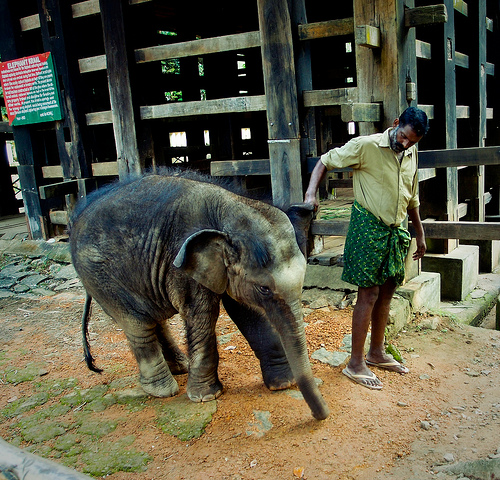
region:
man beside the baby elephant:
[192, 129, 429, 400]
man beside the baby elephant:
[211, 103, 440, 406]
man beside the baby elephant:
[188, 113, 457, 413]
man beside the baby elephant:
[185, 78, 440, 432]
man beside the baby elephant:
[185, 108, 435, 434]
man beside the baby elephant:
[214, 90, 437, 427]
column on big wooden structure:
[0, 0, 52, 240]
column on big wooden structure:
[30, 0, 97, 196]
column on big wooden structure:
[96, 0, 151, 181]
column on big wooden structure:
[254, 0, 306, 243]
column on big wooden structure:
[350, 0, 418, 138]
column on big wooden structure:
[427, 0, 458, 252]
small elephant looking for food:
[73, 173, 330, 425]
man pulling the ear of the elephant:
[305, 93, 433, 388]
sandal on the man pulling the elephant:
[339, 363, 384, 389]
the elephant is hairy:
[60, 171, 362, 471]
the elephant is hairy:
[54, 150, 346, 451]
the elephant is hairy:
[54, 169, 334, 454]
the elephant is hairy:
[57, 178, 334, 438]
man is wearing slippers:
[338, 323, 413, 400]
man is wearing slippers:
[340, 334, 406, 394]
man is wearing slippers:
[330, 340, 407, 397]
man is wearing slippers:
[326, 345, 421, 400]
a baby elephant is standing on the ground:
[67, 166, 329, 421]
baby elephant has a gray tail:
[79, 292, 104, 374]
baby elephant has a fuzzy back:
[69, 166, 242, 251]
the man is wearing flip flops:
[298, 107, 427, 389]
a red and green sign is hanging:
[0, 50, 62, 127]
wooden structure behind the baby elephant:
[1, 0, 497, 325]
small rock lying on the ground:
[417, 418, 430, 429]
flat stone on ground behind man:
[312, 347, 349, 367]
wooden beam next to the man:
[418, 145, 498, 172]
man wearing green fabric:
[339, 201, 410, 288]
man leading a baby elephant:
[303, 105, 428, 389]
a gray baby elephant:
[68, 171, 329, 420]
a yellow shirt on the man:
[319, 124, 421, 227]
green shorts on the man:
[340, 198, 409, 288]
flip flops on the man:
[341, 348, 409, 389]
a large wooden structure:
[0, 0, 499, 283]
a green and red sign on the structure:
[0, 48, 63, 129]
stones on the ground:
[1, 255, 381, 478]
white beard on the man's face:
[390, 125, 406, 152]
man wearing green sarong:
[342, 204, 417, 289]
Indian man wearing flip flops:
[340, 353, 410, 386]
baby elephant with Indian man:
[61, 170, 333, 437]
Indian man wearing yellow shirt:
[318, 125, 425, 217]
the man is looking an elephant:
[259, 98, 441, 442]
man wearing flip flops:
[290, 98, 441, 394]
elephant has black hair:
[58, 156, 328, 424]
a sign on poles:
[3, 52, 69, 139]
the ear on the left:
[169, 223, 241, 305]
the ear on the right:
[281, 199, 331, 265]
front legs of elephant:
[178, 302, 298, 405]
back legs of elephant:
[122, 319, 189, 399]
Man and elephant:
[62, 99, 429, 423]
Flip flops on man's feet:
[341, 353, 410, 389]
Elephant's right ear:
[173, 228, 240, 305]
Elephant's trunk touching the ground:
[264, 304, 324, 421]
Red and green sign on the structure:
[0, 44, 64, 133]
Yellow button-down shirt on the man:
[321, 123, 421, 225]